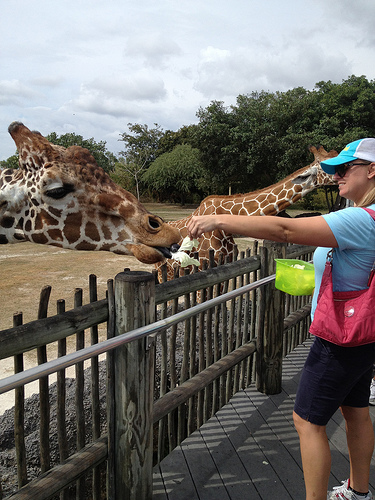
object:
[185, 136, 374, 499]
woman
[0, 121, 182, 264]
giraffe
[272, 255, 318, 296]
object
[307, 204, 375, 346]
purse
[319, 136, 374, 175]
hat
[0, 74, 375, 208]
forest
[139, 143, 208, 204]
trees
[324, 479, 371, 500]
shoe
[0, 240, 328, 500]
fence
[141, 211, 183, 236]
nose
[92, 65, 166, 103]
cloud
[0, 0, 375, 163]
sky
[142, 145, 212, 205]
bush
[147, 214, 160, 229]
big nostril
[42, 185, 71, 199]
dark eye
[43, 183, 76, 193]
long eyelashes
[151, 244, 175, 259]
tongue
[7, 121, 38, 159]
horns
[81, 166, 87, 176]
bumps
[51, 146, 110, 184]
forehead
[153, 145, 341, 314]
giraffe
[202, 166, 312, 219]
crooked neck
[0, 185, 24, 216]
ear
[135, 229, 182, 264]
mouth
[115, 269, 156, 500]
post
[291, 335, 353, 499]
leg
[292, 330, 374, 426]
shorts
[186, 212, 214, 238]
hand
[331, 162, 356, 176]
sunglasses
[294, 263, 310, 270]
giraffe food